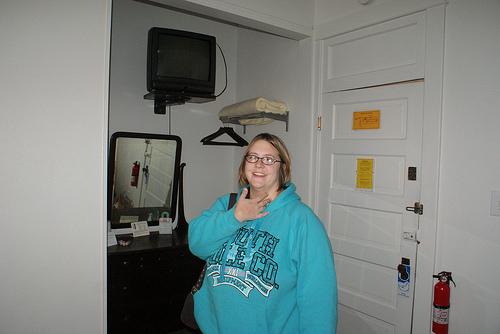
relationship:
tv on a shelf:
[137, 17, 233, 103] [143, 86, 221, 113]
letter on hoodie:
[261, 258, 279, 290] [187, 182, 338, 334]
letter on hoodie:
[252, 252, 263, 277] [187, 182, 338, 334]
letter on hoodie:
[226, 243, 247, 269] [187, 182, 338, 334]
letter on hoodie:
[223, 243, 231, 263] [187, 182, 338, 334]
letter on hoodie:
[208, 246, 218, 261] [187, 182, 338, 334]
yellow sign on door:
[352, 110, 382, 129] [309, 0, 440, 332]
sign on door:
[347, 156, 383, 197] [310, 25, 431, 329]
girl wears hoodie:
[190, 131, 338, 333] [187, 178, 339, 330]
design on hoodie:
[200, 223, 285, 298] [176, 180, 343, 332]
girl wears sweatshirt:
[190, 131, 338, 333] [195, 193, 345, 328]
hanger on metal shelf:
[200, 116, 250, 147] [219, 97, 293, 126]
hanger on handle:
[396, 263, 411, 310] [395, 263, 407, 278]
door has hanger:
[317, 78, 424, 332] [396, 263, 411, 310]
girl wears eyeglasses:
[190, 131, 338, 333] [243, 155, 281, 166]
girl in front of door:
[190, 131, 338, 333] [309, 0, 440, 332]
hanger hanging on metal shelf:
[199, 126, 249, 149] [219, 110, 290, 135]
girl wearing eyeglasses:
[184, 129, 335, 332] [243, 150, 275, 166]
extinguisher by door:
[428, 272, 457, 334] [309, 0, 440, 332]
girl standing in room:
[190, 131, 338, 333] [4, 6, 498, 331]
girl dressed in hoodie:
[190, 131, 338, 333] [187, 182, 338, 334]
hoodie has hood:
[187, 182, 338, 334] [227, 180, 298, 214]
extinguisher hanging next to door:
[428, 272, 457, 334] [335, 10, 441, 323]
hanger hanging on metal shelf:
[200, 116, 250, 147] [219, 110, 290, 135]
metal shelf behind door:
[219, 110, 290, 135] [310, 25, 431, 329]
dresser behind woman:
[110, 234, 194, 304] [181, 135, 360, 317]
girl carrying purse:
[190, 131, 338, 333] [174, 264, 212, 329]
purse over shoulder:
[174, 264, 212, 329] [201, 185, 244, 224]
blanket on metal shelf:
[210, 87, 292, 126] [219, 110, 290, 135]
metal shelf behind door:
[219, 110, 290, 135] [317, 78, 424, 332]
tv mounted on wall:
[147, 27, 220, 97] [111, 3, 308, 235]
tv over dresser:
[147, 27, 220, 97] [109, 222, 245, 332]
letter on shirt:
[231, 224, 254, 244] [165, 112, 372, 332]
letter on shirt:
[261, 257, 281, 290] [183, 194, 348, 329]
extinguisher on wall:
[428, 272, 457, 334] [239, 0, 499, 332]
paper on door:
[352, 108, 382, 131] [317, 78, 424, 332]